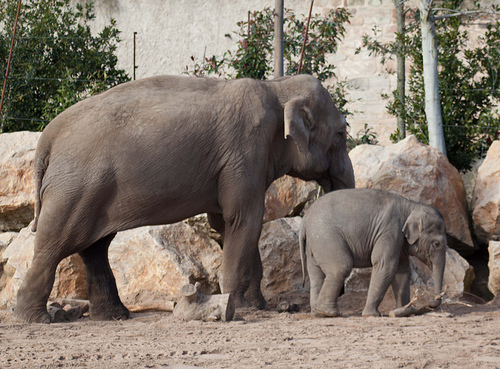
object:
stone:
[0, 129, 48, 234]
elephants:
[11, 73, 356, 327]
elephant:
[293, 185, 448, 317]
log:
[173, 280, 235, 323]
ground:
[0, 298, 499, 368]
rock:
[346, 135, 473, 251]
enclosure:
[0, 36, 499, 368]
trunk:
[429, 259, 445, 308]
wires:
[6, 75, 131, 87]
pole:
[131, 31, 137, 83]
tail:
[29, 137, 52, 232]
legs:
[309, 244, 353, 306]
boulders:
[105, 212, 234, 313]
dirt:
[0, 299, 499, 368]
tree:
[412, 0, 448, 155]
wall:
[0, 1, 499, 138]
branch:
[386, 283, 452, 318]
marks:
[193, 351, 232, 362]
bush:
[353, 0, 500, 175]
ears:
[280, 96, 316, 160]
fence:
[0, 29, 133, 130]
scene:
[0, 1, 499, 368]